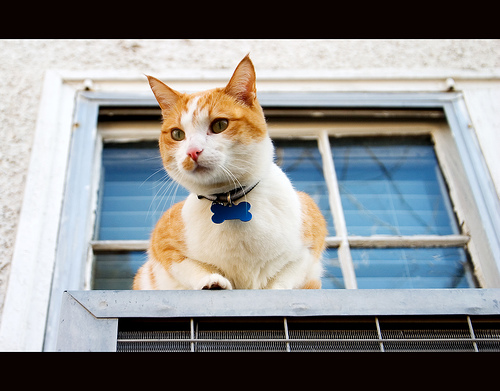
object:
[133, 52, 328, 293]
cat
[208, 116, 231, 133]
eye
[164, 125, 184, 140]
eye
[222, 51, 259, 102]
ear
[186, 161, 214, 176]
mouth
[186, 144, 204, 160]
nose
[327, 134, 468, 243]
window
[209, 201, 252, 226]
tag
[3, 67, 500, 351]
frame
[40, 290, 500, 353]
air conditioner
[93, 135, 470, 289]
blinds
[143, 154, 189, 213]
whisker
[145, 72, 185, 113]
ears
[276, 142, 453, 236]
reflection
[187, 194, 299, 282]
chest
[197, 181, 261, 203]
collar